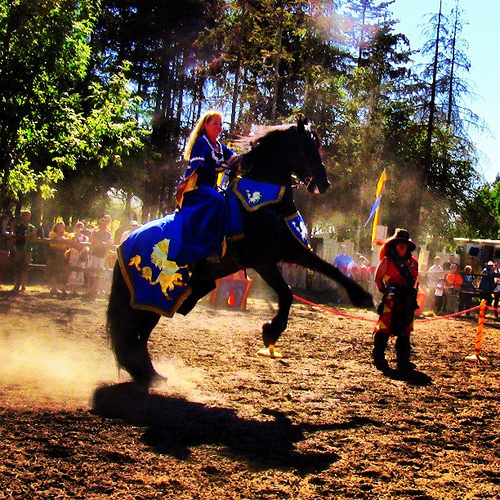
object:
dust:
[398, 185, 442, 235]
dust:
[322, 12, 364, 46]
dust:
[322, 203, 349, 238]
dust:
[82, 195, 124, 219]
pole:
[371, 167, 387, 258]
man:
[370, 228, 419, 373]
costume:
[372, 253, 421, 368]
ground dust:
[6, 351, 121, 411]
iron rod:
[370, 166, 386, 253]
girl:
[371, 227, 420, 371]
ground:
[1, 302, 500, 499]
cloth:
[115, 205, 207, 318]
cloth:
[233, 178, 287, 211]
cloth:
[284, 210, 314, 257]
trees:
[0, 0, 499, 311]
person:
[332, 244, 352, 286]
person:
[10, 209, 36, 293]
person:
[45, 220, 72, 295]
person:
[88, 217, 111, 287]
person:
[426, 255, 445, 312]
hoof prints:
[347, 381, 449, 471]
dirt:
[1, 286, 498, 487]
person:
[63, 222, 90, 297]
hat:
[383, 228, 417, 252]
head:
[396, 241, 409, 253]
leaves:
[0, 0, 149, 206]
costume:
[166, 134, 238, 264]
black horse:
[106, 113, 375, 399]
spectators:
[3, 208, 498, 316]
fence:
[1, 233, 499, 319]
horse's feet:
[152, 370, 168, 384]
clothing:
[117, 175, 315, 318]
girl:
[166, 109, 239, 267]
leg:
[254, 263, 293, 319]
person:
[457, 265, 475, 318]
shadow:
[88, 383, 382, 477]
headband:
[205, 113, 212, 124]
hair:
[181, 110, 223, 161]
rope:
[291, 293, 500, 325]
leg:
[135, 312, 162, 371]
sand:
[72, 332, 319, 463]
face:
[207, 115, 223, 134]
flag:
[364, 167, 388, 251]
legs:
[121, 311, 151, 379]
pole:
[473, 292, 491, 352]